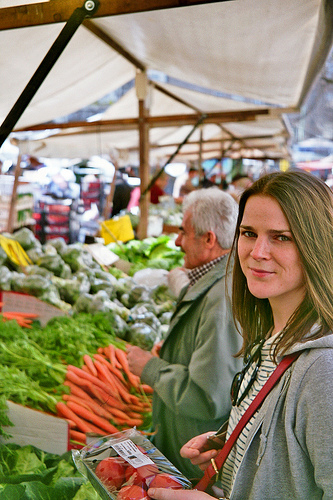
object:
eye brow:
[178, 226, 185, 231]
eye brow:
[239, 223, 255, 230]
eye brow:
[268, 228, 290, 234]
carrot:
[82, 352, 97, 380]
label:
[110, 438, 156, 471]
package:
[70, 424, 195, 499]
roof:
[94, 0, 329, 160]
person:
[145, 170, 332, 497]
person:
[152, 173, 183, 206]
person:
[173, 165, 198, 207]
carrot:
[101, 343, 116, 366]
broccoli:
[70, 265, 127, 317]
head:
[175, 185, 241, 274]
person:
[126, 198, 266, 483]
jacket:
[139, 251, 247, 480]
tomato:
[94, 455, 125, 489]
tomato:
[126, 460, 154, 486]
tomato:
[134, 445, 147, 459]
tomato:
[150, 474, 181, 497]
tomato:
[118, 485, 147, 499]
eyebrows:
[171, 221, 199, 237]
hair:
[224, 168, 332, 369]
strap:
[189, 344, 306, 492]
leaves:
[2, 456, 69, 497]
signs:
[0, 202, 135, 265]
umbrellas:
[1, 2, 330, 163]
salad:
[0, 313, 161, 439]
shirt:
[215, 324, 324, 497]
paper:
[101, 214, 135, 246]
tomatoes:
[94, 443, 184, 499]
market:
[0, 86, 204, 498]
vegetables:
[0, 309, 150, 499]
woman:
[148, 171, 331, 500]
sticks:
[100, 221, 127, 256]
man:
[139, 186, 247, 492]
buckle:
[209, 457, 219, 476]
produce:
[12, 227, 89, 343]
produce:
[1, 219, 155, 411]